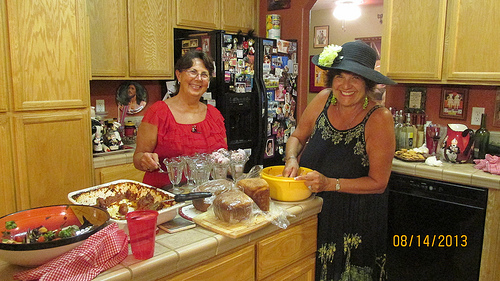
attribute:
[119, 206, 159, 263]
cup — pink 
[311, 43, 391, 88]
hat — black 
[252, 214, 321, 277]
drawer — wood 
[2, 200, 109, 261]
bowl — large 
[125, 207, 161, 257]
cup — pink , plastic 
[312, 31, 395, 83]
hat — black 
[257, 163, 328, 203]
mixing bowl — yellow , plastic 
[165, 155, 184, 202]
sundae dish — empty , glass 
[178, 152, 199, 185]
sundae dish — glass , empty 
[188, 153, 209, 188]
sundae dish — empty , glass 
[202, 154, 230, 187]
sundae dish — glass , empty 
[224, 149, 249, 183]
sundae dish — empty , glass 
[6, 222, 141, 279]
hand towel — red, white, checkered 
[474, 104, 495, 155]
wine bottle — dark green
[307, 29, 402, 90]
hat — large 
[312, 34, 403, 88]
hat — black, woman's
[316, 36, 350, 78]
flower — yellow 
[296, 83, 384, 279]
dress — black 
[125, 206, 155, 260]
cup — empty, red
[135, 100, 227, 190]
shirt — red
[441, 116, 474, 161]
pitcher — red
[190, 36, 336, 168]
fridge — black, double door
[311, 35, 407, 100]
hat — black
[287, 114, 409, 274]
dress — black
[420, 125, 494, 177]
jug — red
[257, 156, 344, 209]
dish — yellow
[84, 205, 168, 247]
cup — red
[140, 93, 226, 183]
top — red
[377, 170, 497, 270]
dish washer — black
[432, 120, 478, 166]
jug — red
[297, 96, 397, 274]
dress — black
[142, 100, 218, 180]
top — red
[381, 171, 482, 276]
dishwasher — black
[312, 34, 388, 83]
hat — black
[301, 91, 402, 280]
dress — black, flowered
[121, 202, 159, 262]
cup — red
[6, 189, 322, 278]
counter — yellow 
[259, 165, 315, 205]
dish — yellow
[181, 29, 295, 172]
fridge — black, double door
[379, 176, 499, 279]
oven door — black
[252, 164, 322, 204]
bowl — yellow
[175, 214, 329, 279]
drawers — brown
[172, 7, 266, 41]
cabinets — brown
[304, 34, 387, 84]
hat — black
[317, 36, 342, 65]
flower — white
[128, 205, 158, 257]
glass — red, plastic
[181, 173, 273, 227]
bread loaves — plastic wrapped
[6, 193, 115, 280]
bowl — large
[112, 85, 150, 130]
jesus painting — round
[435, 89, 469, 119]
painting — wood framed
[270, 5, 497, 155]
wall — red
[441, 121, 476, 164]
pitcher — red, black